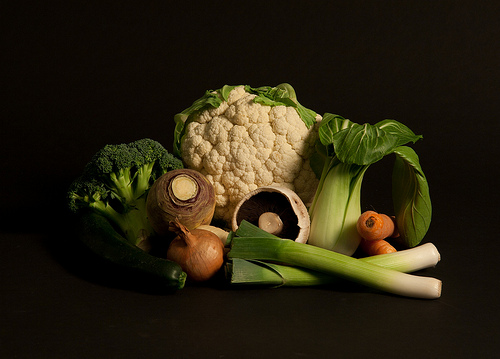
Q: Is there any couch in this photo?
A: No, there are no couches.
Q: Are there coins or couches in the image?
A: No, there are no couches or coins.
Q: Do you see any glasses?
A: No, there are no glasses.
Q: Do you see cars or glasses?
A: No, there are no glasses or cars.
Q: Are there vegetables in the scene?
A: Yes, there are vegetables.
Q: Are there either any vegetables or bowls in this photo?
A: Yes, there are vegetables.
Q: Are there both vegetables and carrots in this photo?
A: Yes, there are both vegetables and carrots.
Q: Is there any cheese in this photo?
A: No, there is no cheese.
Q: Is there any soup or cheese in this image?
A: No, there are no cheese or soup.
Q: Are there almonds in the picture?
A: No, there are no almonds.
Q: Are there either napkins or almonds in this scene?
A: No, there are no almonds or napkins.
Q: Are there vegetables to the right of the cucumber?
A: Yes, there is a vegetable to the right of the cucumber.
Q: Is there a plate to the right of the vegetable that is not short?
A: No, there is a vegetable to the right of the cucumber.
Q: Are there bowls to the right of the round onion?
A: No, there is a vegetable to the right of the onion.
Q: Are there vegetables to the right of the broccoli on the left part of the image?
A: Yes, there is a vegetable to the right of the broccoli.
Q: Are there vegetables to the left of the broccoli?
A: No, the vegetable is to the right of the broccoli.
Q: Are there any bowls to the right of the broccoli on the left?
A: No, there is a vegetable to the right of the broccoli.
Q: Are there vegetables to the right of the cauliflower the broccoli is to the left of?
A: Yes, there is a vegetable to the right of the cauliflower.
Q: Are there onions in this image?
A: Yes, there is an onion.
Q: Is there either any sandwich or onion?
A: Yes, there is an onion.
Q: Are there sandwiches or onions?
A: Yes, there is an onion.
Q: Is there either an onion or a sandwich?
A: Yes, there is an onion.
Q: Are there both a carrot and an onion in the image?
A: Yes, there are both an onion and a carrot.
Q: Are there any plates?
A: No, there are no plates.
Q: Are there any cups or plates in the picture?
A: No, there are no plates or cups.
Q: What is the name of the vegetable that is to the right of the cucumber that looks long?
A: The vegetable is an onion.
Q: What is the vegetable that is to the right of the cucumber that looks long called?
A: The vegetable is an onion.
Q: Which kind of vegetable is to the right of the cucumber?
A: The vegetable is an onion.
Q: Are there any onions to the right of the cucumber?
A: Yes, there is an onion to the right of the cucumber.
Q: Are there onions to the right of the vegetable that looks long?
A: Yes, there is an onion to the right of the cucumber.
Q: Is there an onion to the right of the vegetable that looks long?
A: Yes, there is an onion to the right of the cucumber.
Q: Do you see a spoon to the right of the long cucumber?
A: No, there is an onion to the right of the cucumber.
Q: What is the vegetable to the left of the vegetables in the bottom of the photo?
A: The vegetable is an onion.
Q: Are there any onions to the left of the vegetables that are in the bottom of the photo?
A: Yes, there is an onion to the left of the veggies.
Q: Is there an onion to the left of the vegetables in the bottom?
A: Yes, there is an onion to the left of the veggies.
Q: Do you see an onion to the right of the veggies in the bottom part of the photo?
A: No, the onion is to the left of the veggies.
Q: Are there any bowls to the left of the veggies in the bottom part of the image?
A: No, there is an onion to the left of the veggies.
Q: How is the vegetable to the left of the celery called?
A: The vegetable is an onion.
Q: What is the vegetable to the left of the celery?
A: The vegetable is an onion.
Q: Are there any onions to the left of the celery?
A: Yes, there is an onion to the left of the celery.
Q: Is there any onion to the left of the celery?
A: Yes, there is an onion to the left of the celery.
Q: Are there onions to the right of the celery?
A: No, the onion is to the left of the celery.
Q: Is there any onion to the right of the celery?
A: No, the onion is to the left of the celery.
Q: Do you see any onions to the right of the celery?
A: No, the onion is to the left of the celery.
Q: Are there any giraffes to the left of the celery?
A: No, there is an onion to the left of the celery.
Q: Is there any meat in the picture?
A: No, there is no meat.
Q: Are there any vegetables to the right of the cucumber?
A: Yes, there is a vegetable to the right of the cucumber.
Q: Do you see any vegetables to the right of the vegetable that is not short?
A: Yes, there is a vegetable to the right of the cucumber.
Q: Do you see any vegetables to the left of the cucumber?
A: No, the vegetable is to the right of the cucumber.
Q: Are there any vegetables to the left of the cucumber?
A: No, the vegetable is to the right of the cucumber.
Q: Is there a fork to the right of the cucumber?
A: No, there is a vegetable to the right of the cucumber.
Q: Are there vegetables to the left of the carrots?
A: Yes, there is a vegetable to the left of the carrots.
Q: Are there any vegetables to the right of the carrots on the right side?
A: No, the vegetable is to the left of the carrots.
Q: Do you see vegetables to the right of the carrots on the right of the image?
A: No, the vegetable is to the left of the carrots.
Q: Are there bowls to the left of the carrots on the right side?
A: No, there is a vegetable to the left of the carrots.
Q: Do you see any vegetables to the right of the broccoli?
A: Yes, there is a vegetable to the right of the broccoli.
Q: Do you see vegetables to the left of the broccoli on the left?
A: No, the vegetable is to the right of the broccoli.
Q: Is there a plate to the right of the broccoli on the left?
A: No, there is a vegetable to the right of the broccoli.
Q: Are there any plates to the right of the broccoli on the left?
A: No, there is a vegetable to the right of the broccoli.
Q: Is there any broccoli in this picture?
A: Yes, there is broccoli.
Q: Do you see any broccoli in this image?
A: Yes, there is broccoli.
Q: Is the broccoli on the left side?
A: Yes, the broccoli is on the left of the image.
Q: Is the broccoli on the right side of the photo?
A: No, the broccoli is on the left of the image.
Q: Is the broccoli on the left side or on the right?
A: The broccoli is on the left of the image.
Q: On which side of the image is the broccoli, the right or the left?
A: The broccoli is on the left of the image.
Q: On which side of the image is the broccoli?
A: The broccoli is on the left of the image.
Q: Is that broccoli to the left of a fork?
A: No, the broccoli is to the left of a vegetable.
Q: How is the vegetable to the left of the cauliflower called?
A: The vegetable is broccoli.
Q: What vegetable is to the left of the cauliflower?
A: The vegetable is broccoli.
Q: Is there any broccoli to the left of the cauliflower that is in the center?
A: Yes, there is broccoli to the left of the cauliflower.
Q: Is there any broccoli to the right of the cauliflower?
A: No, the broccoli is to the left of the cauliflower.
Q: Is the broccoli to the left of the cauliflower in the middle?
A: Yes, the broccoli is to the left of the cauliflower.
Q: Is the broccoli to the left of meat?
A: No, the broccoli is to the left of the cauliflower.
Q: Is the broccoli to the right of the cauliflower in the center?
A: No, the broccoli is to the left of the cauliflower.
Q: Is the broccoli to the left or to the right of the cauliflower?
A: The broccoli is to the left of the cauliflower.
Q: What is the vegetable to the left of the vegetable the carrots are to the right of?
A: The vegetable is broccoli.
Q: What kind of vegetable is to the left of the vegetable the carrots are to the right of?
A: The vegetable is broccoli.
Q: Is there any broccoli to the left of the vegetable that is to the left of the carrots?
A: Yes, there is broccoli to the left of the vegetable.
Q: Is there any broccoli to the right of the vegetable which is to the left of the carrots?
A: No, the broccoli is to the left of the vegetable.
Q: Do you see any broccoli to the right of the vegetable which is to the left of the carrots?
A: No, the broccoli is to the left of the vegetable.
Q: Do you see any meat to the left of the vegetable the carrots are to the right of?
A: No, there is broccoli to the left of the vegetable.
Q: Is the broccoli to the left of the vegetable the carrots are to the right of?
A: Yes, the broccoli is to the left of the vegetable.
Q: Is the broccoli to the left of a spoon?
A: No, the broccoli is to the left of the vegetable.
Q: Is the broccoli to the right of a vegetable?
A: No, the broccoli is to the left of a vegetable.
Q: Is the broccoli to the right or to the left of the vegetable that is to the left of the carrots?
A: The broccoli is to the left of the vegetable.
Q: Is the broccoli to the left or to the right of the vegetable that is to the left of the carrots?
A: The broccoli is to the left of the vegetable.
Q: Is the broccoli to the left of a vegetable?
A: Yes, the broccoli is to the left of a vegetable.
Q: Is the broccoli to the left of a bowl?
A: No, the broccoli is to the left of a vegetable.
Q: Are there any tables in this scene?
A: Yes, there is a table.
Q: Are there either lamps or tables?
A: Yes, there is a table.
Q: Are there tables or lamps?
A: Yes, there is a table.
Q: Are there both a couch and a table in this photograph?
A: No, there is a table but no couches.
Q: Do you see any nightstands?
A: No, there are no nightstands.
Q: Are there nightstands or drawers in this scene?
A: No, there are no nightstands or drawers.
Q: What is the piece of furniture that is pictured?
A: The piece of furniture is a table.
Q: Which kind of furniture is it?
A: The piece of furniture is a table.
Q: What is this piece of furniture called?
A: This is a table.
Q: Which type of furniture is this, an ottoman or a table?
A: This is a table.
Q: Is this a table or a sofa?
A: This is a table.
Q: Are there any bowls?
A: No, there are no bowls.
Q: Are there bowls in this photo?
A: No, there are no bowls.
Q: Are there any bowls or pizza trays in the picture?
A: No, there are no bowls or pizza trays.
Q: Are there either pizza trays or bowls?
A: No, there are no bowls or pizza trays.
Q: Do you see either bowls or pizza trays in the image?
A: No, there are no bowls or pizza trays.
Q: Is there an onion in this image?
A: Yes, there is an onion.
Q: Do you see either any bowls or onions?
A: Yes, there is an onion.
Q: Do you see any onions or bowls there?
A: Yes, there is an onion.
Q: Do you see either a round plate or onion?
A: Yes, there is a round onion.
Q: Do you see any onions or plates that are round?
A: Yes, the onion is round.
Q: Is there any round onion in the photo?
A: Yes, there is a round onion.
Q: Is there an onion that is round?
A: Yes, there is an onion that is round.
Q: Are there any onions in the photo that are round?
A: Yes, there is an onion that is round.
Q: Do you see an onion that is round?
A: Yes, there is an onion that is round.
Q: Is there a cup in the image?
A: No, there are no cups.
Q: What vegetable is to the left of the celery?
A: The vegetable is an onion.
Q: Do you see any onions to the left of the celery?
A: Yes, there is an onion to the left of the celery.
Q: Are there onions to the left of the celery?
A: Yes, there is an onion to the left of the celery.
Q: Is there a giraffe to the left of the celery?
A: No, there is an onion to the left of the celery.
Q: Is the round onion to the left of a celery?
A: Yes, the onion is to the left of a celery.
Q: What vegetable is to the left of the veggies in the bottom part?
A: The vegetable is an onion.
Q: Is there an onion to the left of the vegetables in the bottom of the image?
A: Yes, there is an onion to the left of the vegetables.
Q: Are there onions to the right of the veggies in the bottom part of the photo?
A: No, the onion is to the left of the vegetables.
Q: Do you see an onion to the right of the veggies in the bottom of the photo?
A: No, the onion is to the left of the vegetables.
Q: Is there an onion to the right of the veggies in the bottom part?
A: No, the onion is to the left of the vegetables.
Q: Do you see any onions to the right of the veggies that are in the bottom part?
A: No, the onion is to the left of the vegetables.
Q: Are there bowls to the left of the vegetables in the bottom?
A: No, there is an onion to the left of the veggies.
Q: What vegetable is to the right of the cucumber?
A: The vegetable is an onion.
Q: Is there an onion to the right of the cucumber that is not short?
A: Yes, there is an onion to the right of the cucumber.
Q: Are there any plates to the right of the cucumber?
A: No, there is an onion to the right of the cucumber.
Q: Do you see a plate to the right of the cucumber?
A: No, there is an onion to the right of the cucumber.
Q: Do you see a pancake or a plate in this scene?
A: No, there are no plates or pancakes.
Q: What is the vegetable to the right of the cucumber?
A: The vegetable is a celery.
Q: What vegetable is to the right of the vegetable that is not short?
A: The vegetable is a celery.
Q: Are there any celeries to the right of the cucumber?
A: Yes, there is a celery to the right of the cucumber.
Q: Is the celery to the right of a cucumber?
A: Yes, the celery is to the right of a cucumber.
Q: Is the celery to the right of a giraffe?
A: No, the celery is to the right of a cucumber.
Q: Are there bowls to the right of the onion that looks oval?
A: No, there is a celery to the right of the onion.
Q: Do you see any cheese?
A: No, there is no cheese.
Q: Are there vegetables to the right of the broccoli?
A: Yes, there is a vegetable to the right of the broccoli.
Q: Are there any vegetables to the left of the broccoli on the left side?
A: No, the vegetable is to the right of the broccoli.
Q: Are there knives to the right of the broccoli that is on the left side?
A: No, there is a vegetable to the right of the broccoli.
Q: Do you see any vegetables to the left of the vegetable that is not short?
A: No, the vegetable is to the right of the cucumber.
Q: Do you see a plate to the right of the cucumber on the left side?
A: No, there is a vegetable to the right of the cucumber.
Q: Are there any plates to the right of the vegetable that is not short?
A: No, there is a vegetable to the right of the cucumber.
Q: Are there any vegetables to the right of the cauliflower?
A: Yes, there is a vegetable to the right of the cauliflower.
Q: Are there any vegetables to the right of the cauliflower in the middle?
A: Yes, there is a vegetable to the right of the cauliflower.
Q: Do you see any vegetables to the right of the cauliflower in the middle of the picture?
A: Yes, there is a vegetable to the right of the cauliflower.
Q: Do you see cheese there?
A: No, there is no cheese.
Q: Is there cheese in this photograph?
A: No, there is no cheese.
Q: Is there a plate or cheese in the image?
A: No, there are no cheese or plates.